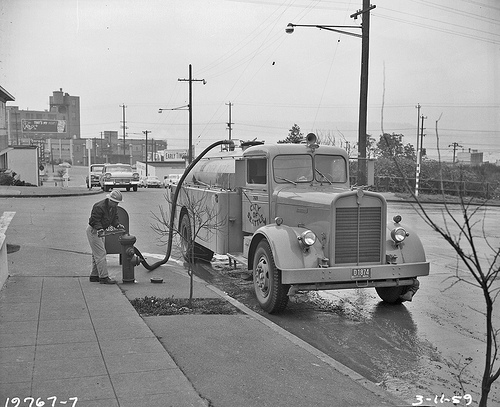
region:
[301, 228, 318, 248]
a light on a truck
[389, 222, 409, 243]
a light on a truck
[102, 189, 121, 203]
a hat on a head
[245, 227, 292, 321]
the tire of a truck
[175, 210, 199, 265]
the tire of a truck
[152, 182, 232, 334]
a dead tree on the street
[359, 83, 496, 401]
a dead tree on the street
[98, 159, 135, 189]
a car in the street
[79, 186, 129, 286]
a man standing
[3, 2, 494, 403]
a black and white photo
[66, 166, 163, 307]
fireman hooking up water hose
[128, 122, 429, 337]
old fire truck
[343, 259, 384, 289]
antique license plate number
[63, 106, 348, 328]
fireman using a water hydrant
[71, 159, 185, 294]
man in hard hat getting water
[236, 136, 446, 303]
front end of old fire truck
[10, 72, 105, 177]
building in black and white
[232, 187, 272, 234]
city logo on truck door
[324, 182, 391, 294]
front fender of old fire truck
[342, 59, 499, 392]
trees without leaves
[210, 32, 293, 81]
overhead electrical poles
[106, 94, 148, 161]
large black electrical pole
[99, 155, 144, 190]
old fashioned car on road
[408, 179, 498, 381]
bare tree without leaves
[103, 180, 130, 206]
large helmet on man's head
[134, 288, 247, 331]
large bed of gravel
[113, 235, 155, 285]
fire hydrant on street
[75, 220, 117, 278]
man wearing tan pants with creases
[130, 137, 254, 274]
large black hose leading from truck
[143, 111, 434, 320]
large truck with white headlights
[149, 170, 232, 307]
DRY SMALL TREE ON CURB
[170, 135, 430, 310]
WATER TRUCK PARKED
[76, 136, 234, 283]
MAN FILLING HYDRANT WITH WATER HOSE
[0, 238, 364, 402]
PAVED SIDE WALK CURB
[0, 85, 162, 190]
TALL BUILDINGS IN THE CITY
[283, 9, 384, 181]
LAMP POST ON THE SIDE OF THE ROAD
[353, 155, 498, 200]
DRY BUSHES ON THE SIDE OF THE ROAD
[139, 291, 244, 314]
PATCH OF GRASS AROUND THE TREE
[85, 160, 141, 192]
TWO CARS PARKED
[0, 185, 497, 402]
TAR ROAD COVERED WITH WATER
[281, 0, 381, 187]
light pole beside truck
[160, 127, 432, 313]
truck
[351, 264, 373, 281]
the license plate is on the front of the truck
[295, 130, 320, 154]
the truck's horn is on top of the truck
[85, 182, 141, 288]
a man is working on the fire hydrant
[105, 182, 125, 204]
the man is wearing a hat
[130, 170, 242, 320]
a tree is planted in the sidewalk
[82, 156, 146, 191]
two cars parked on the road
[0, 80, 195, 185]
buildings in the background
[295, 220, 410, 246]
the truck has two headlights